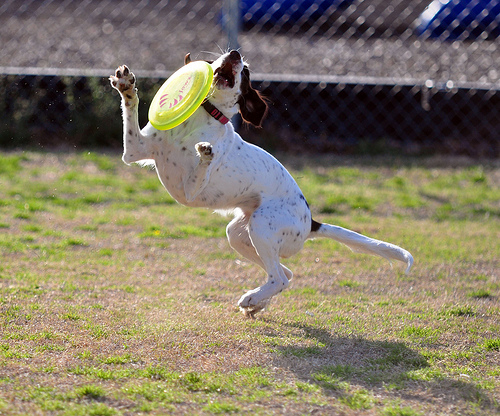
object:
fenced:
[2, 3, 498, 159]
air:
[53, 26, 447, 391]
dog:
[101, 35, 421, 325]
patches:
[84, 248, 220, 373]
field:
[6, 161, 496, 413]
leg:
[184, 130, 220, 200]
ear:
[243, 70, 267, 125]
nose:
[215, 44, 253, 72]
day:
[42, 20, 464, 400]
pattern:
[154, 80, 188, 107]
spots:
[264, 190, 314, 215]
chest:
[164, 160, 251, 220]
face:
[187, 41, 255, 117]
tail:
[311, 213, 419, 283]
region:
[296, 201, 312, 258]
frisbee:
[150, 60, 215, 123]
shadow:
[281, 307, 465, 414]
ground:
[220, 327, 289, 357]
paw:
[231, 292, 258, 322]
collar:
[201, 100, 232, 128]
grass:
[2, 149, 492, 413]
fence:
[4, 1, 497, 181]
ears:
[228, 62, 270, 132]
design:
[152, 78, 192, 111]